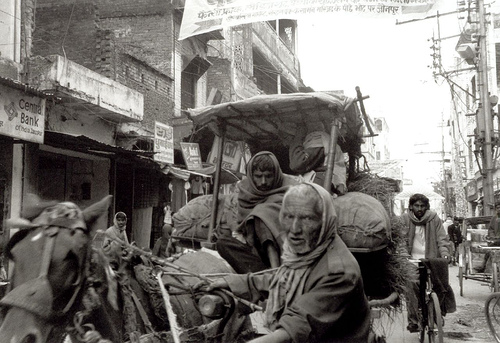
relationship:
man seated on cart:
[231, 150, 311, 273] [161, 90, 371, 304]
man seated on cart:
[191, 180, 369, 342] [161, 90, 371, 304]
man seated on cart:
[394, 192, 452, 331] [161, 90, 371, 304]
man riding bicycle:
[394, 192, 452, 331] [402, 255, 454, 342]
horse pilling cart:
[21, 211, 262, 326] [158, 41, 425, 261]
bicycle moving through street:
[374, 260, 461, 325] [399, 249, 499, 331]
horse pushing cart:
[0, 191, 256, 342] [167, 89, 387, 287]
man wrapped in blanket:
[231, 150, 311, 273] [224, 145, 314, 267]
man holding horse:
[191, 180, 369, 342] [0, 191, 256, 342]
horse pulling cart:
[0, 191, 256, 342] [0, 89, 421, 342]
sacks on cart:
[334, 190, 396, 247] [171, 92, 403, 335]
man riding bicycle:
[394, 192, 452, 331] [408, 267, 455, 342]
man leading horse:
[191, 180, 372, 342] [0, 191, 256, 342]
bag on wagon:
[168, 191, 229, 242] [170, 87, 410, 327]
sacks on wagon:
[332, 189, 397, 253] [170, 87, 410, 327]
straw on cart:
[343, 170, 403, 197] [0, 89, 421, 342]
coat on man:
[394, 211, 455, 312] [394, 194, 451, 331]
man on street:
[394, 192, 452, 331] [12, 236, 498, 341]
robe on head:
[278, 176, 337, 270] [276, 181, 337, 254]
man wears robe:
[191, 180, 372, 342] [278, 176, 337, 270]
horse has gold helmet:
[0, 191, 256, 342] [2, 195, 108, 343]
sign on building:
[179, 135, 214, 180] [9, 9, 401, 253]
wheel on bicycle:
[414, 287, 469, 340] [411, 253, 451, 342]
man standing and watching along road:
[101, 210, 136, 248] [438, 257, 475, 329]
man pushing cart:
[191, 180, 369, 342] [171, 92, 403, 335]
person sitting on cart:
[287, 116, 336, 186] [171, 92, 403, 335]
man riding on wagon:
[447, 215, 463, 266] [171, 91, 401, 341]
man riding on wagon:
[394, 194, 451, 331] [171, 91, 401, 341]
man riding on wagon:
[191, 180, 372, 342] [171, 91, 401, 341]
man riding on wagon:
[238, 150, 303, 270] [171, 91, 401, 341]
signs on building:
[0, 55, 242, 174] [1, 1, 313, 297]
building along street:
[1, 1, 313, 297] [372, 267, 497, 342]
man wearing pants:
[394, 192, 452, 331] [408, 260, 447, 324]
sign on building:
[1, 83, 43, 145] [2, 2, 303, 249]